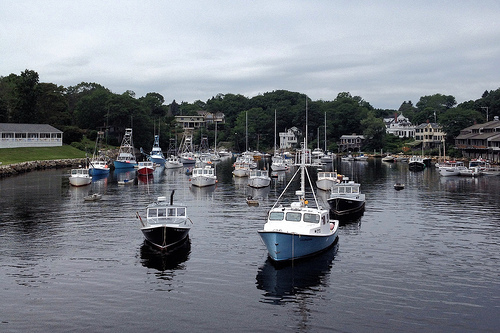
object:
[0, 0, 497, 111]
clouds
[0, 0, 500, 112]
sky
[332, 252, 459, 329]
ripples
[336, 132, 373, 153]
house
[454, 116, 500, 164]
building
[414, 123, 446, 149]
building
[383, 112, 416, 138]
building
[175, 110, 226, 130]
building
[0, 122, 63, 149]
building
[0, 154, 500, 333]
river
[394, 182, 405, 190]
boat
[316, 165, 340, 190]
boat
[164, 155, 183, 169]
boat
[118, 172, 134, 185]
boat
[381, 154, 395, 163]
boat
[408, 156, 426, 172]
boat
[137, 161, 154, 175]
boat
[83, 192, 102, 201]
boat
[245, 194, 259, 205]
boat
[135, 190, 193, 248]
boat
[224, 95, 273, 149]
trees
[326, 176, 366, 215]
boat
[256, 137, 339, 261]
boat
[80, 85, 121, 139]
trees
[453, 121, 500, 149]
roof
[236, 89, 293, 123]
leaves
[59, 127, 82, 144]
leaves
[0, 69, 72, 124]
tree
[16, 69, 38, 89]
leaves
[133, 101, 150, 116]
leaves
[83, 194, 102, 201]
small boat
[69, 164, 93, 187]
boat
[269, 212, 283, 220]
window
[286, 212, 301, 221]
window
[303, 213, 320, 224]
window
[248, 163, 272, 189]
boat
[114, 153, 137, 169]
boat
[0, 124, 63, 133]
roof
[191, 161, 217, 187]
boat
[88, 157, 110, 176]
boat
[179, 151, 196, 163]
boat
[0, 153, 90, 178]
bank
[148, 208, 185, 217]
windows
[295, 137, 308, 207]
mast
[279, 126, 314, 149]
building